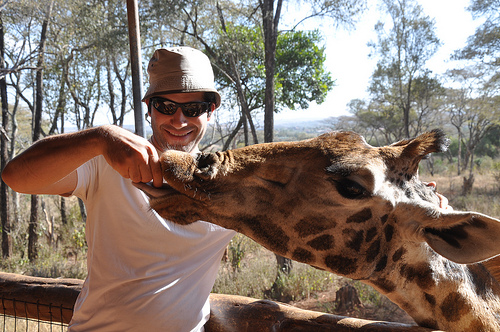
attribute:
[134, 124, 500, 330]
giraffe — in the picture, brown, spotted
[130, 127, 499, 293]
head — large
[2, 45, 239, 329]
man — in the picture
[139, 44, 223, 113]
hat — tan, khaki, large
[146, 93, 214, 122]
sunglasses — black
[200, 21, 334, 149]
tree — leafy, tall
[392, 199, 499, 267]
ear — brown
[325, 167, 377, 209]
eye — black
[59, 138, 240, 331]
t-shirt — white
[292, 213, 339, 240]
spot — brown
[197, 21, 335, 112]
leaves — green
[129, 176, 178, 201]
tongue — small